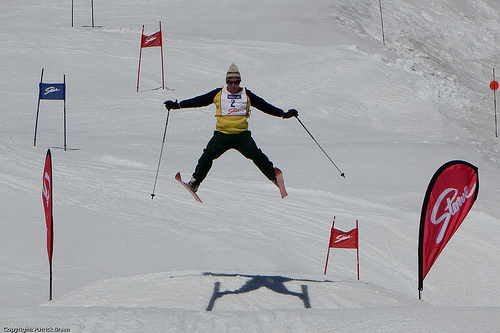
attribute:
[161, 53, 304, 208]
man — jumping, standing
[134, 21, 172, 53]
flag — red, white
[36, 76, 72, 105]
flag — blue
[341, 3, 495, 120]
snow — bumpy, white, fresh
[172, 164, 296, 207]
skis — red